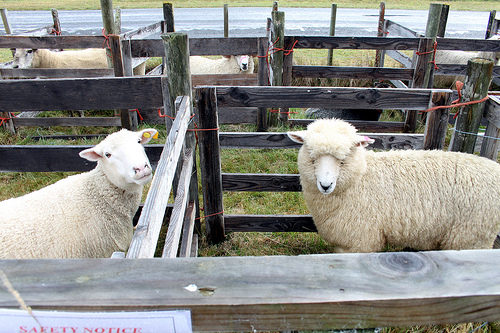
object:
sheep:
[288, 108, 500, 249]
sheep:
[151, 37, 253, 100]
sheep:
[9, 47, 113, 73]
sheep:
[0, 121, 164, 268]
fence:
[4, 0, 499, 330]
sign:
[3, 302, 193, 332]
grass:
[0, 44, 491, 262]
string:
[4, 17, 491, 238]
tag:
[141, 128, 162, 141]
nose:
[133, 160, 152, 174]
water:
[0, 8, 500, 52]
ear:
[138, 127, 161, 145]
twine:
[1, 266, 42, 331]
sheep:
[297, 80, 394, 119]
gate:
[282, 30, 426, 135]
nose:
[316, 180, 335, 191]